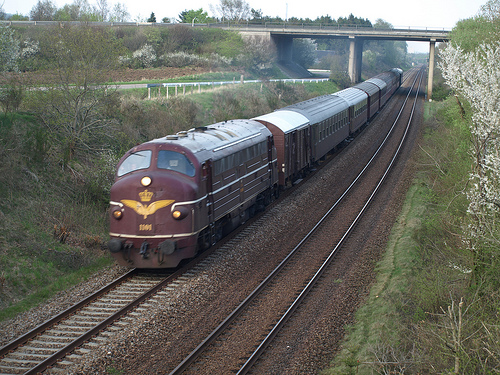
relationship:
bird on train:
[119, 196, 173, 218] [103, 65, 406, 270]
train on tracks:
[103, 66, 406, 270] [50, 279, 168, 363]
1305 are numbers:
[135, 218, 158, 230] [133, 210, 155, 229]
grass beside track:
[376, 101, 474, 347] [20, 60, 424, 356]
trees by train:
[6, 19, 132, 222] [103, 65, 406, 270]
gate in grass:
[90, 76, 327, 93] [63, 62, 315, 94]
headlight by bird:
[171, 206, 189, 220] [117, 194, 169, 219]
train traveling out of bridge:
[103, 65, 406, 270] [237, 20, 463, 101]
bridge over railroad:
[237, 20, 463, 101] [3, 63, 427, 367]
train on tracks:
[103, 65, 406, 270] [3, 67, 427, 361]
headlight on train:
[114, 207, 121, 218] [103, 65, 406, 270]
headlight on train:
[171, 204, 184, 217] [103, 65, 406, 270]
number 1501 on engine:
[139, 223, 152, 231] [107, 117, 281, 270]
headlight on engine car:
[141, 176, 148, 184] [112, 119, 279, 272]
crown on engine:
[137, 189, 153, 202] [107, 117, 281, 270]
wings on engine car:
[119, 200, 173, 216] [112, 119, 279, 272]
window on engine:
[155, 142, 190, 180] [106, 119, 276, 269]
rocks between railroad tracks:
[118, 279, 208, 359] [2, 259, 209, 362]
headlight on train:
[112, 210, 122, 220] [103, 65, 406, 270]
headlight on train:
[171, 206, 189, 220] [103, 65, 406, 270]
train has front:
[103, 65, 406, 270] [109, 145, 201, 273]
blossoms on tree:
[439, 41, 485, 150] [435, 37, 485, 267]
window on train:
[113, 145, 149, 176] [103, 65, 406, 270]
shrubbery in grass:
[36, 210, 76, 259] [5, 151, 121, 292]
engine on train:
[106, 119, 276, 269] [103, 65, 406, 270]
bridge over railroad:
[219, 20, 453, 102] [3, 63, 427, 367]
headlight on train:
[140, 176, 153, 187] [103, 65, 406, 270]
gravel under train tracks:
[73, 63, 425, 373] [169, 65, 424, 374]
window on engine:
[156, 149, 197, 177] [106, 119, 276, 269]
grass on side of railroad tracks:
[318, 68, 500, 375] [0, 64, 426, 374]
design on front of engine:
[119, 196, 179, 220] [106, 119, 276, 269]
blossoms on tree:
[436, 36, 499, 218] [365, 17, 499, 373]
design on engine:
[120, 189, 176, 220] [106, 119, 276, 269]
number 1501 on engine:
[136, 220, 156, 232] [106, 119, 276, 269]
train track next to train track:
[0, 266, 183, 373] [167, 71, 424, 373]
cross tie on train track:
[8, 349, 70, 365] [0, 266, 183, 373]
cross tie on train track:
[30, 340, 91, 352] [0, 266, 183, 373]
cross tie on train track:
[46, 326, 112, 337] [0, 266, 183, 373]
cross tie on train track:
[70, 312, 129, 326] [0, 266, 183, 373]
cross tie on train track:
[91, 296, 152, 308] [0, 266, 183, 373]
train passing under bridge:
[103, 65, 406, 270] [219, 20, 453, 102]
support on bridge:
[346, 33, 362, 83] [219, 20, 453, 102]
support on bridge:
[425, 36, 438, 100] [219, 20, 453, 102]